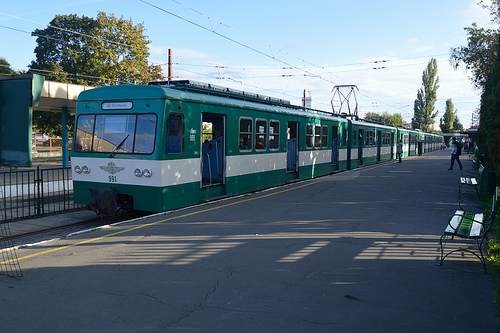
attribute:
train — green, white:
[55, 80, 425, 221]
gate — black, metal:
[5, 161, 64, 223]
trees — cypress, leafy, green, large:
[411, 57, 444, 126]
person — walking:
[444, 135, 468, 173]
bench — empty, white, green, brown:
[453, 161, 490, 194]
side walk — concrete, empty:
[288, 190, 401, 242]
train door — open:
[197, 107, 230, 187]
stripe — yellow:
[139, 213, 187, 221]